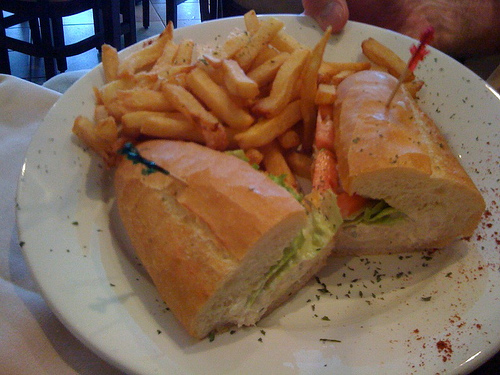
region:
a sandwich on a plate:
[22, 16, 487, 358]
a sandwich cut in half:
[92, 50, 494, 342]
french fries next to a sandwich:
[66, 29, 488, 345]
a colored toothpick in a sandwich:
[351, 11, 446, 184]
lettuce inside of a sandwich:
[106, 136, 344, 327]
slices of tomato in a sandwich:
[306, 64, 490, 252]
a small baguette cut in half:
[92, 62, 488, 341]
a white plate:
[13, 8, 496, 370]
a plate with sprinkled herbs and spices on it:
[21, 10, 494, 365]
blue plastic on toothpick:
[118, 139, 189, 189]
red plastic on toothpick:
[382, 22, 436, 106]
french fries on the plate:
[70, 9, 426, 191]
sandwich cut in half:
[102, 66, 486, 344]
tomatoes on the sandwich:
[308, 104, 365, 217]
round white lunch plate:
[12, 11, 498, 371]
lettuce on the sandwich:
[226, 113, 404, 323]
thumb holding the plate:
[299, 0, 351, 36]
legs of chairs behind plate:
[0, 0, 188, 75]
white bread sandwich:
[107, 63, 485, 338]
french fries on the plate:
[88, 23, 352, 143]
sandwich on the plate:
[93, 123, 338, 330]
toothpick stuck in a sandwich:
[114, 140, 203, 200]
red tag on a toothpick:
[396, 26, 437, 78]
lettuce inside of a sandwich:
[226, 145, 333, 335]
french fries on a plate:
[88, 25, 415, 185]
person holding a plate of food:
[293, 1, 496, 82]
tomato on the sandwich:
[307, 90, 360, 205]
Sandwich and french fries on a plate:
[103, 55, 486, 327]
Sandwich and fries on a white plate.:
[14, 7, 499, 367]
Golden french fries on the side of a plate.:
[67, 24, 394, 195]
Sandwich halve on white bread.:
[97, 135, 332, 343]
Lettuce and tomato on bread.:
[316, 71, 489, 273]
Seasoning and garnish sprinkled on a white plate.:
[303, 250, 491, 369]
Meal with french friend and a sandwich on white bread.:
[72, 10, 493, 344]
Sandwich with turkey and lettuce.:
[111, 131, 332, 335]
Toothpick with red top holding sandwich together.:
[315, 17, 486, 262]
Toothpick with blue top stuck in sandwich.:
[108, 137, 328, 344]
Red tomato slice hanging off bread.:
[313, 65, 485, 270]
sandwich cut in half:
[111, 70, 486, 339]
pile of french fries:
[73, 7, 427, 192]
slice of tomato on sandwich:
[313, 104, 369, 219]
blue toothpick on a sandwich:
[121, 141, 191, 190]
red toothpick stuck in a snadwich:
[381, 28, 438, 109]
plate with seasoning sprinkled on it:
[21, 14, 493, 374]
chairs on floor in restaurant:
[1, 0, 210, 72]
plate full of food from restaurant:
[16, 11, 497, 372]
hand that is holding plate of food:
[300, 1, 498, 54]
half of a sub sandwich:
[114, 139, 336, 336]